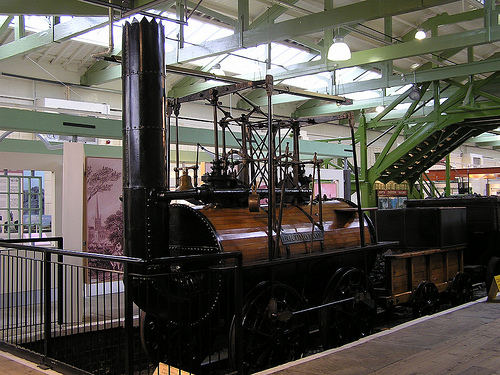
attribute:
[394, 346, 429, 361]
pathway — grey, tan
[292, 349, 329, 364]
lines — white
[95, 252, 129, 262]
rail — black, metal, green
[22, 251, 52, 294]
rod — grey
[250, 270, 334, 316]
engine — black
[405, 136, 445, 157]
steps — green, under, black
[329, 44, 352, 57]
lights — hanging, metal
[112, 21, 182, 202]
chimney — black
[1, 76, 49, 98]
wall — white, edge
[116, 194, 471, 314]
train — metal, wooden, black, display, wood, vintage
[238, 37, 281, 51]
bar — metal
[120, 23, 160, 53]
pipe — black, metal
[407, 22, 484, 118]
beams — green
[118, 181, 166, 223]
metal — square, black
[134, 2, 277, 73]
windows — sun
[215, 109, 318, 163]
fence — black